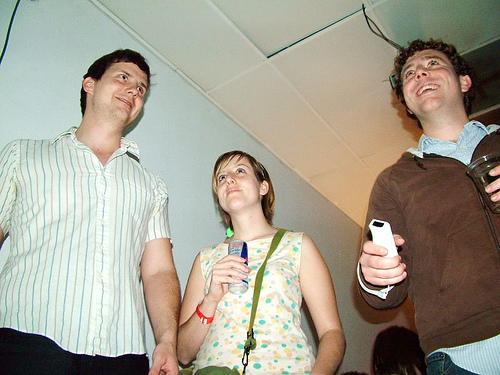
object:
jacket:
[349, 128, 500, 317]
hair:
[394, 38, 472, 129]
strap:
[249, 229, 288, 317]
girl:
[176, 150, 347, 373]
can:
[218, 240, 249, 295]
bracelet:
[195, 305, 214, 325]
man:
[0, 47, 180, 317]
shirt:
[0, 125, 173, 359]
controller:
[367, 218, 401, 265]